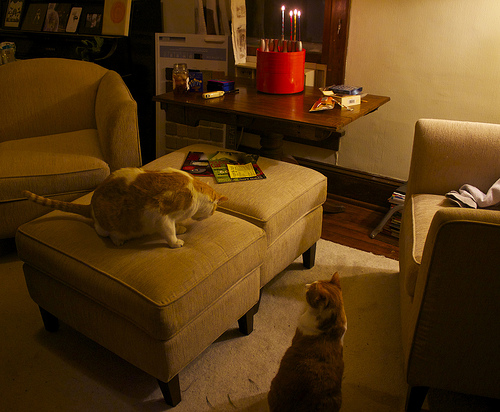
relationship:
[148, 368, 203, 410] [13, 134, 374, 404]
leg of chair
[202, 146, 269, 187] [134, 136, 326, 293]
magazine on chair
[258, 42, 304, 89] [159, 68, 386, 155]
cup on table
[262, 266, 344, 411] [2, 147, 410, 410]
cat on floor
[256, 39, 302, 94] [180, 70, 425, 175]
cup on table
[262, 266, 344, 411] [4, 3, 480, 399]
cat in house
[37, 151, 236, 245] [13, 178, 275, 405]
cat sitting on an chair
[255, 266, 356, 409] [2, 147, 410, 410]
cat sitting on floor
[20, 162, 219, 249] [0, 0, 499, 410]
cat in living room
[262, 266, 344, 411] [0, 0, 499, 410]
cat in living room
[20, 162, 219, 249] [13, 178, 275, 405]
cat on an chair